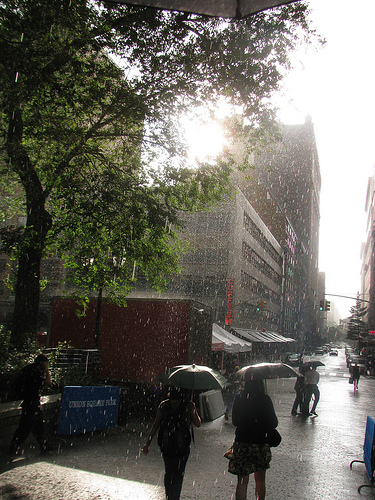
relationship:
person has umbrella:
[141, 387, 200, 500] [164, 361, 234, 398]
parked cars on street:
[311, 337, 362, 363] [323, 354, 343, 365]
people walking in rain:
[224, 380, 279, 499] [9, 4, 373, 499]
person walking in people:
[141, 387, 200, 500] [224, 380, 279, 499]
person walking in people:
[14, 348, 66, 460] [224, 380, 279, 499]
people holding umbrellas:
[224, 380, 279, 499] [154, 360, 302, 401]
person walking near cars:
[351, 362, 359, 390] [348, 353, 366, 375]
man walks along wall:
[298, 362, 324, 418] [1, 394, 74, 464]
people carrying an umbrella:
[224, 380, 279, 499] [235, 361, 305, 378]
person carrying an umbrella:
[141, 387, 200, 500] [154, 361, 227, 389]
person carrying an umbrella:
[138, 385, 201, 498] [170, 362, 230, 427]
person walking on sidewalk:
[347, 359, 363, 393] [1, 378, 373, 498]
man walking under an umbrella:
[304, 366, 320, 415] [296, 358, 327, 371]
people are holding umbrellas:
[159, 378, 327, 485] [169, 350, 316, 400]